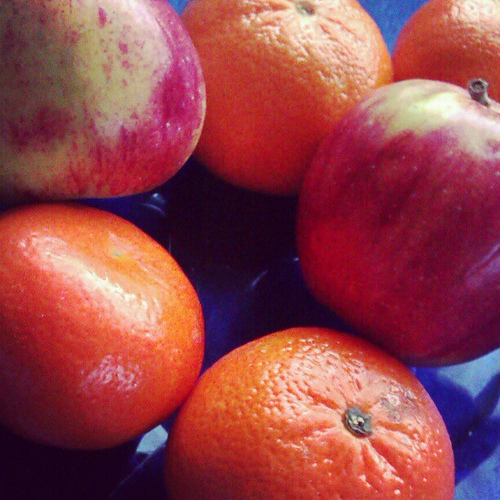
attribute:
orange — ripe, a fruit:
[162, 321, 467, 498]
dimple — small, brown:
[344, 409, 371, 436]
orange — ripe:
[175, 3, 401, 196]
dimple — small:
[290, 4, 320, 22]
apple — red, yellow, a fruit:
[291, 76, 499, 372]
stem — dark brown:
[466, 74, 494, 112]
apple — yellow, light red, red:
[1, 2, 205, 203]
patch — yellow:
[362, 80, 494, 167]